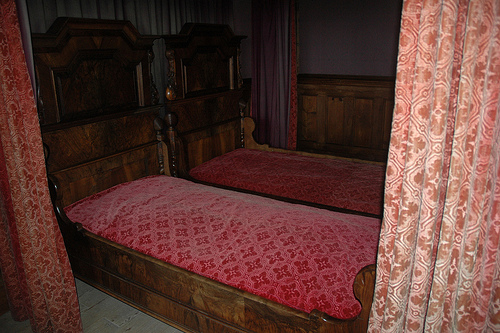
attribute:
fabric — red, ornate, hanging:
[0, 1, 83, 331]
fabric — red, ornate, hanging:
[367, 4, 499, 331]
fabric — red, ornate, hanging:
[78, 174, 376, 314]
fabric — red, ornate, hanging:
[197, 142, 387, 214]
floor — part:
[5, 274, 182, 329]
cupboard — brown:
[290, 78, 400, 164]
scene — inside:
[17, 10, 452, 317]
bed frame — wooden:
[37, 95, 373, 325]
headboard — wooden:
[26, 16, 160, 203]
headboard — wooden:
[164, 18, 266, 175]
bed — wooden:
[30, 52, 382, 331]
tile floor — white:
[0, 272, 187, 330]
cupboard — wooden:
[288, 68, 392, 164]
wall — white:
[289, 0, 404, 84]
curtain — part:
[402, 211, 484, 283]